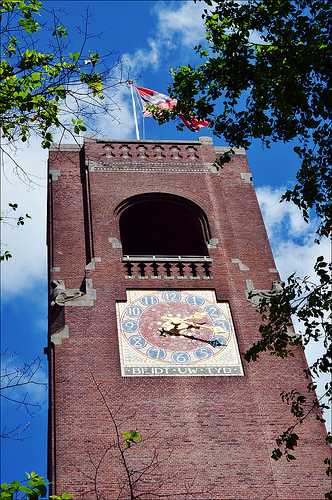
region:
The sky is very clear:
[81, 7, 148, 54]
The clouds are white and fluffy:
[4, 136, 44, 215]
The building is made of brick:
[132, 391, 272, 484]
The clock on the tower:
[119, 292, 232, 366]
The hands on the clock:
[164, 308, 229, 341]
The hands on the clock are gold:
[158, 308, 231, 342]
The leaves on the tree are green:
[209, 8, 326, 117]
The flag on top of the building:
[122, 70, 217, 143]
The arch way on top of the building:
[99, 189, 223, 283]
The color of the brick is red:
[117, 391, 252, 472]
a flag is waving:
[135, 85, 208, 131]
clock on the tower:
[115, 287, 244, 377]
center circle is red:
[139, 302, 211, 348]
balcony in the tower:
[119, 193, 211, 276]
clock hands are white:
[169, 311, 225, 334]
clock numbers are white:
[123, 292, 227, 361]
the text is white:
[130, 367, 231, 372]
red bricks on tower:
[48, 151, 331, 499]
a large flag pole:
[128, 80, 139, 139]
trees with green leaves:
[0, 0, 331, 499]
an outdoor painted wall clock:
[118, 287, 229, 359]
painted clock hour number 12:
[160, 288, 178, 299]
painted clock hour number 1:
[185, 292, 200, 303]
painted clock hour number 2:
[204, 302, 220, 314]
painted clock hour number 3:
[212, 316, 226, 331]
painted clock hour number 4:
[209, 334, 224, 345]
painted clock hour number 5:
[195, 344, 208, 357]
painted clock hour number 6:
[171, 349, 185, 360]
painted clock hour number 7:
[147, 346, 160, 357]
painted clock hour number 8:
[128, 334, 144, 347]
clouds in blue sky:
[3, 2, 328, 486]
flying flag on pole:
[129, 79, 217, 140]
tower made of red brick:
[46, 140, 327, 494]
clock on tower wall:
[119, 287, 239, 376]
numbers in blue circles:
[123, 291, 229, 363]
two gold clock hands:
[167, 310, 225, 336]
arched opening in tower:
[115, 190, 213, 263]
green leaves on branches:
[0, 0, 121, 187]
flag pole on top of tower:
[127, 79, 137, 139]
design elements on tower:
[101, 143, 199, 166]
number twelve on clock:
[164, 286, 180, 308]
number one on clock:
[183, 292, 203, 308]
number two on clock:
[207, 306, 221, 318]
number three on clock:
[215, 320, 227, 333]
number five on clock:
[198, 346, 209, 361]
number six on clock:
[176, 352, 187, 363]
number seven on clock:
[148, 347, 162, 359]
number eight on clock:
[128, 335, 145, 349]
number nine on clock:
[124, 319, 137, 331]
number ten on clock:
[127, 306, 141, 316]